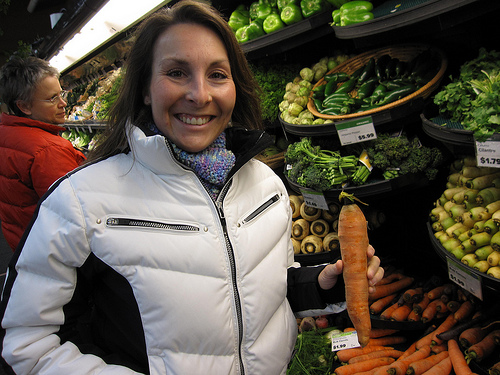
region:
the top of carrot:
[338, 186, 374, 212]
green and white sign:
[325, 123, 382, 144]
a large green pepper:
[325, 2, 375, 29]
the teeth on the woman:
[174, 107, 219, 130]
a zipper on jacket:
[103, 207, 207, 242]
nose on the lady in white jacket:
[190, 72, 215, 107]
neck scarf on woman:
[190, 152, 222, 187]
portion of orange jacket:
[12, 135, 52, 177]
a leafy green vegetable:
[442, 65, 497, 113]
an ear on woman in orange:
[12, 97, 37, 122]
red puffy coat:
[2, 112, 90, 254]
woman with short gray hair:
[0, 49, 55, 114]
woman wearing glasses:
[33, 90, 65, 105]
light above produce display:
[46, 0, 171, 74]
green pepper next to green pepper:
[280, 7, 297, 22]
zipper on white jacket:
[108, 216, 201, 232]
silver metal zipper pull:
[215, 202, 228, 220]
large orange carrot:
[337, 191, 375, 348]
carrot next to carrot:
[447, 339, 473, 374]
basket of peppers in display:
[307, 41, 450, 123]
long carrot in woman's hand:
[323, 195, 384, 341]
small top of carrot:
[325, 178, 362, 200]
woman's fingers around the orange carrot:
[323, 241, 393, 298]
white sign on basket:
[340, 120, 400, 151]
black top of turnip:
[300, 237, 320, 259]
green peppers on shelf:
[264, 10, 364, 36]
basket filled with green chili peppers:
[305, 47, 455, 150]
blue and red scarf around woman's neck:
[160, 142, 249, 183]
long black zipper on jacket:
[192, 196, 269, 345]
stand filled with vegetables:
[308, 59, 498, 274]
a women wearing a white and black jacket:
[65, 15, 404, 372]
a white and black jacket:
[47, 112, 349, 365]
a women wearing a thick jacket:
[59, 15, 268, 373]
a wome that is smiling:
[98, 0, 333, 358]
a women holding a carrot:
[78, 7, 396, 373]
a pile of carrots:
[361, 266, 486, 373]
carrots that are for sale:
[344, 270, 464, 373]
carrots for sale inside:
[289, 207, 488, 374]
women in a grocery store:
[77, 3, 397, 364]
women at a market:
[19, 5, 410, 328]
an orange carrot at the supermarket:
[338, 183, 380, 348]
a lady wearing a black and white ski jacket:
[0, 122, 323, 374]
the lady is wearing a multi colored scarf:
[168, 134, 238, 183]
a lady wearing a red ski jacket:
[1, 51, 85, 243]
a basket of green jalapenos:
[308, 42, 445, 117]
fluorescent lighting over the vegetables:
[49, 1, 166, 74]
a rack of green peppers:
[230, 0, 321, 37]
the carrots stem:
[336, 184, 369, 206]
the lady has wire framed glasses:
[29, 88, 74, 105]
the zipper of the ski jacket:
[213, 202, 245, 373]